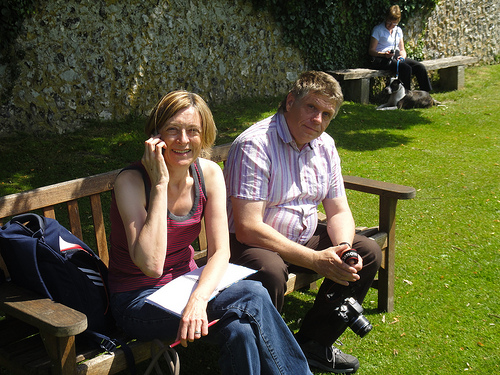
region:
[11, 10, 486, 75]
a stone wall behind the people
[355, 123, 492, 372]
the grass under the benches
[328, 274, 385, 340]
a black camera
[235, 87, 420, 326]
a man sitting on a bench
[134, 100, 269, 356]
a lady wearing a pink shirt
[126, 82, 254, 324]
a lady holding a cell phone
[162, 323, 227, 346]
a pen in the ladys hand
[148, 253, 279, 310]
a notebook on the ladys lap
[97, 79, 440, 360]
two people sitting on a bench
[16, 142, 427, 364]
a wooden bench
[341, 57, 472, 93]
a cement bench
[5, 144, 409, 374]
a wooden bench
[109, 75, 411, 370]
two people sitting on a bench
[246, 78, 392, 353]
a man holding a camera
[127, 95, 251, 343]
a lady on a cell phone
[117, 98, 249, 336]
a lady wearing a pink shirt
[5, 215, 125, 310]
a blue bag on the bench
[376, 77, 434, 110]
a dog laying on the grass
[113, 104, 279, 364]
a lady holding a notebook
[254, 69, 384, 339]
a man in a striped shirt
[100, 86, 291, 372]
the woman beside the man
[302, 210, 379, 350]
the man holding the camera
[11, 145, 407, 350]
the bench is wooden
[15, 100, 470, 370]
the bench on the grass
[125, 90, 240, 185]
the woman on the phone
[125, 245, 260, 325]
the book in the woman's lap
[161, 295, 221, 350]
the woman holding the pencil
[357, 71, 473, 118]
the dog beside the woman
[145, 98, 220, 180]
the woman is smiling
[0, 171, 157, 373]
part of a wooden bench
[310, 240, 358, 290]
the hand of a man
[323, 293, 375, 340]
a large black camera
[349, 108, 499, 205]
a section of green grass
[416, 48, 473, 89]
part of a concrete bench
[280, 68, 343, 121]
a man's short cut brown hair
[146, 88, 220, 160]
a woman's short cut brown hair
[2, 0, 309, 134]
part of a stone wall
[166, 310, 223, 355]
a pink pencil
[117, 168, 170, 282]
the arm of a woman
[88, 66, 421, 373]
two people on a bench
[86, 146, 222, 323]
a pink and gray tank top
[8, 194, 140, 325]
a blue back pack by woman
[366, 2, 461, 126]
a woman sitting with her dog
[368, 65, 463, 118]
a black and white dog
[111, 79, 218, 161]
a woman on a cellphone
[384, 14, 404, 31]
glasses on woman's face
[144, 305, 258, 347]
a pencil in her hand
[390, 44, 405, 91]
blue leash to dog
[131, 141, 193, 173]
woman is holding cell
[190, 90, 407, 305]
man has striped shirt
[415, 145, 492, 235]
green and short grass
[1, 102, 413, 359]
people sitting on bench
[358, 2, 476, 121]
woman is sitting in distance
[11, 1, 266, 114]
grey and stone wall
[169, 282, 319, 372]
woman has blue jeans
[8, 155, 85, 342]
blue bag on bench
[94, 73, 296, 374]
a woman talking on a phone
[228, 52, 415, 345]
man holding a camera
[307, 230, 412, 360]
black camera with a strap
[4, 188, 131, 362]
blue backpack on a bench